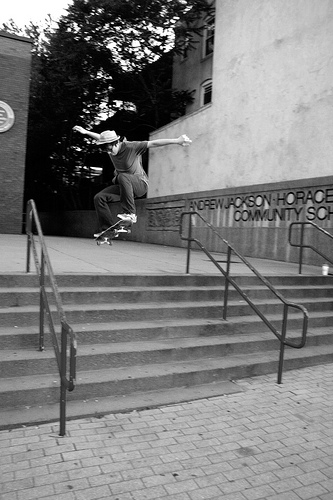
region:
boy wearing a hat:
[64, 108, 199, 249]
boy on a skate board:
[71, 101, 187, 257]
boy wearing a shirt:
[72, 108, 198, 249]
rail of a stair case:
[28, 197, 84, 386]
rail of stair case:
[179, 202, 306, 351]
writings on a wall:
[196, 191, 306, 214]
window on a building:
[194, 11, 216, 63]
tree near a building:
[59, 17, 136, 101]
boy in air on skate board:
[65, 100, 170, 248]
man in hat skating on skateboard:
[67, 117, 191, 235]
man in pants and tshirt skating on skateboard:
[66, 115, 190, 235]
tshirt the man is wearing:
[103, 135, 150, 184]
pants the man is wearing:
[91, 176, 147, 224]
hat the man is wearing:
[93, 128, 121, 146]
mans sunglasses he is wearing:
[101, 145, 114, 154]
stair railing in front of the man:
[21, 194, 76, 439]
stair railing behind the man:
[176, 207, 312, 388]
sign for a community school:
[189, 184, 331, 226]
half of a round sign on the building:
[0, 97, 14, 135]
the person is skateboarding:
[72, 122, 189, 246]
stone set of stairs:
[2, 266, 332, 427]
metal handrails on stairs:
[21, 194, 332, 437]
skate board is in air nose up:
[91, 218, 131, 246]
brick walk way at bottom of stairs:
[0, 363, 332, 499]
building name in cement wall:
[189, 182, 332, 226]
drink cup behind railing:
[320, 261, 329, 278]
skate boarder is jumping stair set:
[71, 120, 193, 249]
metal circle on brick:
[0, 98, 15, 134]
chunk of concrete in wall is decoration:
[142, 199, 188, 234]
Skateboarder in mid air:
[69, 123, 193, 246]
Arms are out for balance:
[70, 124, 192, 150]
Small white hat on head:
[94, 128, 120, 146]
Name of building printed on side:
[188, 186, 332, 225]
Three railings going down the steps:
[20, 198, 331, 436]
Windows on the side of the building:
[174, 7, 213, 110]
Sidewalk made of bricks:
[1, 360, 332, 497]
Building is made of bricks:
[1, 29, 37, 234]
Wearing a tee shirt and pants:
[90, 140, 148, 232]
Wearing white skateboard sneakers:
[115, 210, 139, 224]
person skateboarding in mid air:
[67, 119, 196, 250]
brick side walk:
[106, 425, 222, 491]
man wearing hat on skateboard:
[73, 123, 190, 250]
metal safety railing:
[176, 204, 307, 390]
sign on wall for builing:
[185, 184, 331, 231]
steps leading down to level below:
[3, 270, 331, 379]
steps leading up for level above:
[0, 270, 332, 382]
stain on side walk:
[229, 442, 260, 460]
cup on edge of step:
[318, 259, 331, 279]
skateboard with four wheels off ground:
[92, 219, 134, 246]